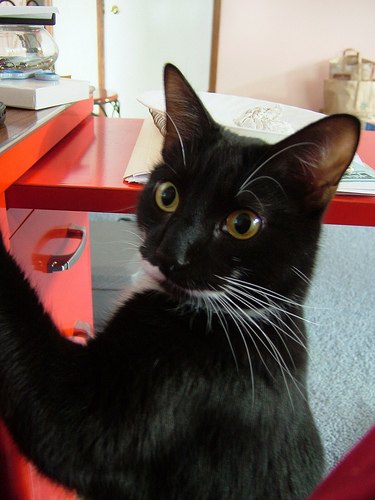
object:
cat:
[0, 64, 361, 499]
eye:
[224, 209, 262, 241]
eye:
[152, 180, 179, 212]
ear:
[288, 112, 361, 209]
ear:
[163, 65, 214, 156]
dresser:
[0, 86, 94, 500]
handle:
[45, 222, 87, 272]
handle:
[74, 320, 94, 338]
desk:
[0, 79, 374, 226]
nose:
[159, 247, 186, 265]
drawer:
[9, 211, 92, 500]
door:
[99, 0, 215, 120]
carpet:
[88, 213, 374, 487]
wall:
[216, 1, 375, 116]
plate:
[0, 76, 89, 112]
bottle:
[0, 24, 59, 70]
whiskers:
[237, 142, 324, 216]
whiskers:
[159, 109, 184, 176]